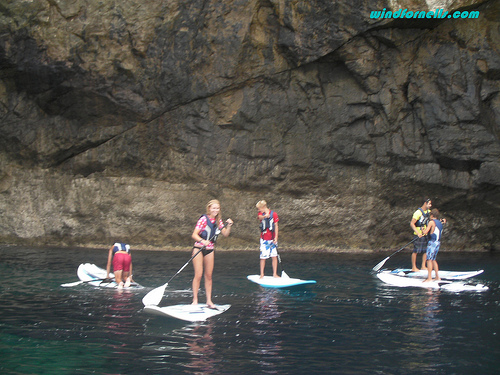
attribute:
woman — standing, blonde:
[190, 198, 235, 303]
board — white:
[142, 304, 234, 322]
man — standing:
[409, 197, 447, 273]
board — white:
[392, 267, 483, 280]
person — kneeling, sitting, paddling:
[105, 237, 135, 289]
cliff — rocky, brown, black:
[2, 2, 496, 257]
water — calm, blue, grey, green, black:
[0, 246, 497, 371]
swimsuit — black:
[191, 244, 213, 254]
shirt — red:
[257, 211, 279, 240]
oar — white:
[141, 245, 201, 308]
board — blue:
[248, 272, 315, 289]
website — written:
[369, 5, 479, 20]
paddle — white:
[372, 239, 409, 272]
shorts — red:
[112, 252, 131, 271]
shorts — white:
[258, 237, 277, 257]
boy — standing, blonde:
[256, 198, 280, 279]